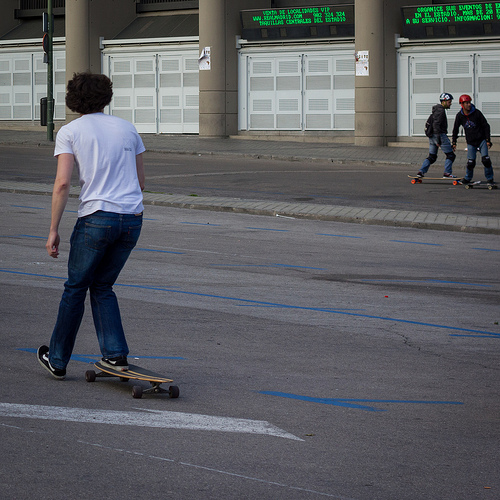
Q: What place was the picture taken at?
A: It was taken at the street.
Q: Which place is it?
A: It is a street.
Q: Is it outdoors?
A: Yes, it is outdoors.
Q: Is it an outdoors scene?
A: Yes, it is outdoors.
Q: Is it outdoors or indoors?
A: It is outdoors.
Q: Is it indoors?
A: No, it is outdoors.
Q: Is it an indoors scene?
A: No, it is outdoors.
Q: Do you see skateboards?
A: Yes, there is a skateboard.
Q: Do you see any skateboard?
A: Yes, there is a skateboard.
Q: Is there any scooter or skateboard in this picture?
A: Yes, there is a skateboard.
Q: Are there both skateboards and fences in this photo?
A: No, there is a skateboard but no fences.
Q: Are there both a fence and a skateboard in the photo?
A: No, there is a skateboard but no fences.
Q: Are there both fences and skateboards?
A: No, there is a skateboard but no fences.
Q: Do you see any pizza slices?
A: No, there are no pizza slices.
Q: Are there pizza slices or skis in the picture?
A: No, there are no pizza slices or skis.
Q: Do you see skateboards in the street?
A: Yes, there is a skateboard in the street.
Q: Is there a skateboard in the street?
A: Yes, there is a skateboard in the street.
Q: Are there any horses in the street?
A: No, there is a skateboard in the street.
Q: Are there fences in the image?
A: No, there are no fences.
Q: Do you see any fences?
A: No, there are no fences.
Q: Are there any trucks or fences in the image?
A: No, there are no fences or trucks.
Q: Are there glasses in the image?
A: No, there are no glasses.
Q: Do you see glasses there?
A: No, there are no glasses.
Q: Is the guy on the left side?
A: Yes, the guy is on the left of the image.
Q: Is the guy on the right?
A: No, the guy is on the left of the image.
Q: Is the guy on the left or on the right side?
A: The guy is on the left of the image.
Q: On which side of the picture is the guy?
A: The guy is on the left of the image.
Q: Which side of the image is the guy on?
A: The guy is on the left of the image.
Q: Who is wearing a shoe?
A: The guy is wearing a shoe.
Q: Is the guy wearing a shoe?
A: Yes, the guy is wearing a shoe.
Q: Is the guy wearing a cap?
A: No, the guy is wearing a shoe.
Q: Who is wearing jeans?
A: The guy is wearing jeans.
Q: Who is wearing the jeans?
A: The guy is wearing jeans.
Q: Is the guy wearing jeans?
A: Yes, the guy is wearing jeans.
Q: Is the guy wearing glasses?
A: No, the guy is wearing jeans.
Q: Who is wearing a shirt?
A: The guy is wearing a shirt.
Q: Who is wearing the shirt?
A: The guy is wearing a shirt.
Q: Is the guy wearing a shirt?
A: Yes, the guy is wearing a shirt.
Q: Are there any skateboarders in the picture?
A: Yes, there is a skateboarder.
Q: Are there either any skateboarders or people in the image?
A: Yes, there is a skateboarder.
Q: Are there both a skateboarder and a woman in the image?
A: No, there is a skateboarder but no women.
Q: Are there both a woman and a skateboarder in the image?
A: No, there is a skateboarder but no women.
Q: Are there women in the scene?
A: No, there are no women.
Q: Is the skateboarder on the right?
A: Yes, the skateboarder is on the right of the image.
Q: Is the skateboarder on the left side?
A: No, the skateboarder is on the right of the image.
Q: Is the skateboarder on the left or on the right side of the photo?
A: The skateboarder is on the right of the image.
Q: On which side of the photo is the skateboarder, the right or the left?
A: The skateboarder is on the right of the image.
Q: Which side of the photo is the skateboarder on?
A: The skateboarder is on the right of the image.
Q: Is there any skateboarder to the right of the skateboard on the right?
A: Yes, there is a skateboarder to the right of the skateboard.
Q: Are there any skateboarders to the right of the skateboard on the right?
A: Yes, there is a skateboarder to the right of the skateboard.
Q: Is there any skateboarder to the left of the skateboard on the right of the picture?
A: No, the skateboarder is to the right of the skateboard.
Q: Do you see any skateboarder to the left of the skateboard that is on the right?
A: No, the skateboarder is to the right of the skateboard.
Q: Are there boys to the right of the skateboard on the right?
A: No, there is a skateboarder to the right of the skateboard.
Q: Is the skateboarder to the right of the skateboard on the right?
A: Yes, the skateboarder is to the right of the skateboard.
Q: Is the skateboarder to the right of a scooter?
A: No, the skateboarder is to the right of the skateboard.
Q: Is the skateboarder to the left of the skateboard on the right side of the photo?
A: No, the skateboarder is to the right of the skateboard.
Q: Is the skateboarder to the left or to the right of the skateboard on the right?
A: The skateboarder is to the right of the skateboard.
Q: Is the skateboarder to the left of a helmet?
A: No, the skateboarder is to the right of a helmet.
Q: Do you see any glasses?
A: No, there are no glasses.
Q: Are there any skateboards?
A: Yes, there is a skateboard.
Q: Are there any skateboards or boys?
A: Yes, there is a skateboard.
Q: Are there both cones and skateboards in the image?
A: No, there is a skateboard but no cones.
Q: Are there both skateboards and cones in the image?
A: No, there is a skateboard but no cones.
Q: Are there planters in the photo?
A: No, there are no planters.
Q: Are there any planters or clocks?
A: No, there are no planters or clocks.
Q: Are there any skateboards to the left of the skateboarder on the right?
A: Yes, there is a skateboard to the left of the skateboarder.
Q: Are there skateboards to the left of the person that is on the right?
A: Yes, there is a skateboard to the left of the skateboarder.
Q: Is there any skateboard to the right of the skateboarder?
A: No, the skateboard is to the left of the skateboarder.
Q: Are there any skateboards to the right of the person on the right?
A: No, the skateboard is to the left of the skateboarder.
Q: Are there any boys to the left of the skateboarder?
A: No, there is a skateboard to the left of the skateboarder.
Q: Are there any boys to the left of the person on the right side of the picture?
A: No, there is a skateboard to the left of the skateboarder.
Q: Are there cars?
A: No, there are no cars.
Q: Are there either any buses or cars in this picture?
A: No, there are no cars or buses.